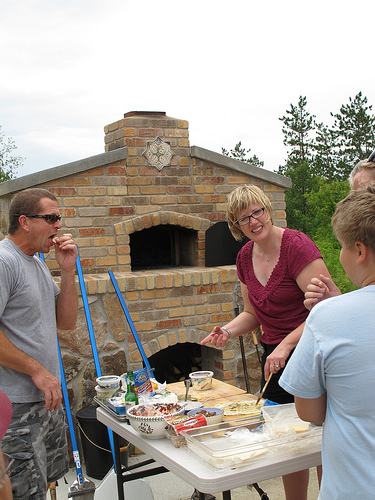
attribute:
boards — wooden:
[159, 371, 275, 429]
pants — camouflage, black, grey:
[0, 391, 72, 499]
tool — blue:
[26, 247, 95, 499]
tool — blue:
[71, 243, 155, 498]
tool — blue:
[107, 267, 219, 499]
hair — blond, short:
[224, 185, 274, 240]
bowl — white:
[127, 400, 183, 440]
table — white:
[96, 372, 322, 499]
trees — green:
[220, 92, 375, 241]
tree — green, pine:
[273, 95, 324, 176]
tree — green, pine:
[318, 91, 374, 181]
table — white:
[88, 370, 352, 496]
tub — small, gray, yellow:
[73, 402, 130, 483]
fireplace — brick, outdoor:
[128, 327, 241, 458]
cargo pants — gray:
[3, 395, 72, 498]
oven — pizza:
[0, 106, 302, 414]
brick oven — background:
[1, 107, 298, 394]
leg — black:
[104, 428, 135, 498]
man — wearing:
[2, 184, 77, 394]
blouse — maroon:
[233, 226, 324, 346]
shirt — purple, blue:
[234, 228, 326, 341]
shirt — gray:
[1, 232, 65, 406]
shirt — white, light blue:
[279, 280, 373, 498]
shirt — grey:
[1, 238, 72, 400]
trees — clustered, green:
[274, 92, 374, 174]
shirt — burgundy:
[239, 221, 327, 368]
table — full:
[74, 336, 344, 493]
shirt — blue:
[277, 283, 363, 499]